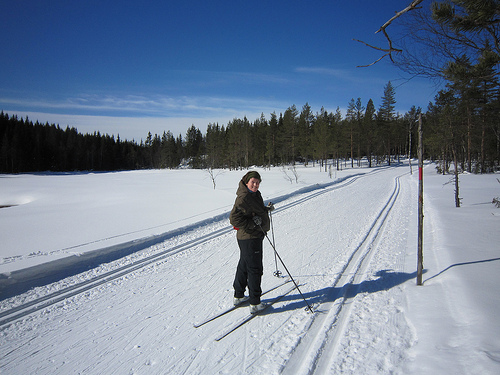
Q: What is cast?
A: Shadows.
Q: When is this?
A: Daytime.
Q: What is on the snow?
A: Tracks.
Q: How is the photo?
A: Clear.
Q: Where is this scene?
A: On a ski trail.